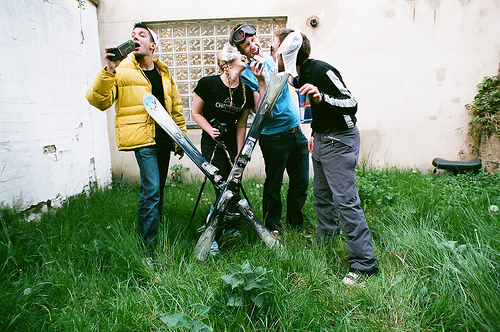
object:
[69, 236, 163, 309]
grass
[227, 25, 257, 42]
goggles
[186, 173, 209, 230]
pole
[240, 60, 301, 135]
shirt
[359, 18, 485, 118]
wall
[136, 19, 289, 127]
window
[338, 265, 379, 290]
shoes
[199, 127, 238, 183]
pants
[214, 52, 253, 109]
hair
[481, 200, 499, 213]
flower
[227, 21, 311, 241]
man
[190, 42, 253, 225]
woman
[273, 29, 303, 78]
brassiere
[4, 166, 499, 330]
yard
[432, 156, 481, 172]
seat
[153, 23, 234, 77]
tiles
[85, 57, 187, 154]
jacket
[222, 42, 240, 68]
hat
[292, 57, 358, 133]
sweater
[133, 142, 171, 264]
jeans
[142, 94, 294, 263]
skis